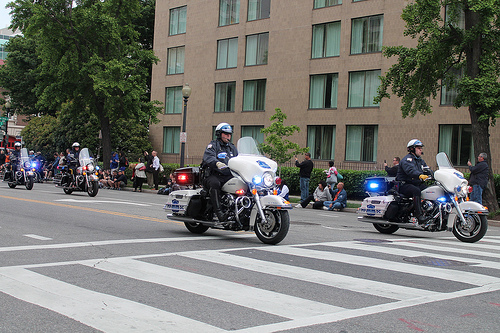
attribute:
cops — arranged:
[17, 117, 446, 199]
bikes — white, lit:
[12, 147, 493, 247]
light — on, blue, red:
[366, 178, 385, 193]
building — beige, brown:
[147, 0, 499, 201]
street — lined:
[1, 175, 500, 330]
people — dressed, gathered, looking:
[31, 150, 355, 203]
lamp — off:
[173, 83, 194, 178]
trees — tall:
[16, 7, 492, 170]